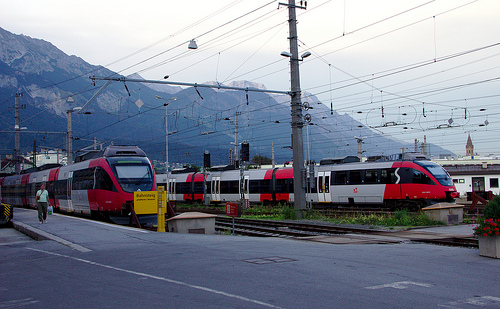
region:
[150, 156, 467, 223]
a red and gray electric train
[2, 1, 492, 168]
train wires above the trains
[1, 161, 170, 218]
transit train waiting for passengers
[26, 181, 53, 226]
person walking away from the train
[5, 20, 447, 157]
tall mountains in the background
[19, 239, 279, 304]
white line painted on the ground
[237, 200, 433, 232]
grass growing next to the train tracks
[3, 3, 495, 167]
the wires connect to the trains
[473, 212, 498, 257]
planter with red flowers inside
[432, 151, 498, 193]
white building on the side of the train tracks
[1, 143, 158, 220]
a train on a track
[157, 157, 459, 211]
a train is on a track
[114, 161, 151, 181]
a window on a train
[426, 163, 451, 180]
a window on a train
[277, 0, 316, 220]
a tall metal pole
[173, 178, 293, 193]
a stretch of windows on a train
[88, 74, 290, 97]
a metal rod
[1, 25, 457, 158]
a ridge of mountains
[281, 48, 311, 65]
lights on a post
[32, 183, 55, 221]
a person is walking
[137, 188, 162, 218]
yellow bumper on left train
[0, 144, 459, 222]
red and white trains on tracks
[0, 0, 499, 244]
wires connected by utility poles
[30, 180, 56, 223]
person walking on left platform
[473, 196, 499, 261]
rose bush in lower right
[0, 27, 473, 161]
rocky mountains behind trains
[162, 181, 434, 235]
grass patches between tracks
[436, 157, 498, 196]
white and brown building behind right train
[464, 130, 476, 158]
tower in right background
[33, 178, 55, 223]
passenger carrying bag in left hand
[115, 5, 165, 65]
white clouds in blue sky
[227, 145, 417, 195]
red and white train cars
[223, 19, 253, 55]
white clouds in blue sky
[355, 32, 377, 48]
white clouds in blue sky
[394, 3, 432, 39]
white clouds in blue sky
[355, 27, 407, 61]
white clouds in blue sky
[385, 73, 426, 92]
white clouds in blue sky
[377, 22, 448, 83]
white clouds in blue sky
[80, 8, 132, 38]
white clouds in blue sky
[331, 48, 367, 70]
white clouds in blue sky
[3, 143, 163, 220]
Grey and red train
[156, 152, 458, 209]
Grey and red train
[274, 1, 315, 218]
Tall grey wire pole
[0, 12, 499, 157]
Walls suspended in the air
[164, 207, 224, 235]
Sunken structure with brown roof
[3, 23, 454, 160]
Beautiful mountains in the background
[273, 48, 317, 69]
Two white lights on pole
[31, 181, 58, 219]
Person in white shirt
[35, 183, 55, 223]
Person walking on sidewalk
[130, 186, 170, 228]
Yellow sign post in front of train